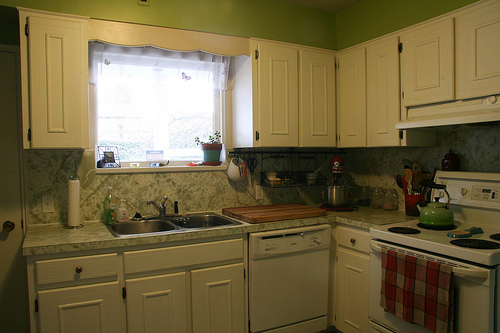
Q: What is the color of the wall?
A: Green.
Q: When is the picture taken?
A: Daytime.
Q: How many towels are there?
A: 1.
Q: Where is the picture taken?
A: Kitchen.